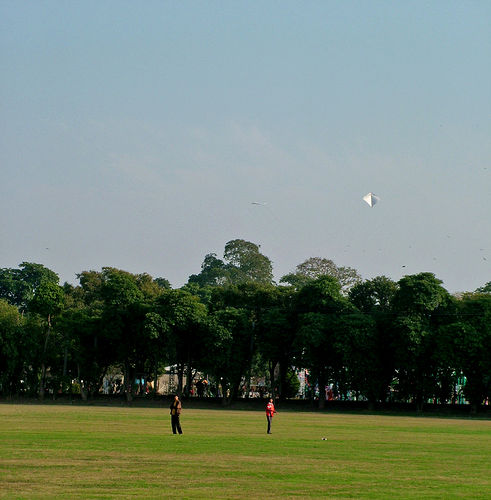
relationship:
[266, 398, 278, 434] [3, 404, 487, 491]
body standing in field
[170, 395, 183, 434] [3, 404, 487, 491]
body standing in field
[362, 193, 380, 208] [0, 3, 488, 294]
kite in sky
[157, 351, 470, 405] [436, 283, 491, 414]
buildings through tree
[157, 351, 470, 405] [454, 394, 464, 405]
buildings with shutters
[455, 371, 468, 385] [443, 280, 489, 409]
shutters by tree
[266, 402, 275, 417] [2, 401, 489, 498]
jacket on grass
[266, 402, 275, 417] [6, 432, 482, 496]
jacket on grass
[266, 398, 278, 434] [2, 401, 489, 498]
body on grass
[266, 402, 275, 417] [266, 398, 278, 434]
jacket on body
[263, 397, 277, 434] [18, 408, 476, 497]
body on grass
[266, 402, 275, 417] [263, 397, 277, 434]
jacket on body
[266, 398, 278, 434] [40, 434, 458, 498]
body on grass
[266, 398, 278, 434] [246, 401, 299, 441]
body wearing jacket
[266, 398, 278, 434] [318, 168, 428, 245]
body flying kite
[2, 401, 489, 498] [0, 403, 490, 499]
grass in field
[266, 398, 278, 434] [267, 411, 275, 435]
body wearing jeans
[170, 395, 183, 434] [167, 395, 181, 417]
body wearing jacket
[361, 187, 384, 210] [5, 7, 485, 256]
kite in sky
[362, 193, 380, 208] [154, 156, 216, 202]
kite in sky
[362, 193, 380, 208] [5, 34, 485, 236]
kite in sky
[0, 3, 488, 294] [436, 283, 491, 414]
sky over tree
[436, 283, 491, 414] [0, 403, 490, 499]
tree in field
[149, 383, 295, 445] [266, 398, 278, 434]
sun on body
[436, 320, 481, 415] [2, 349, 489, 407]
tree along side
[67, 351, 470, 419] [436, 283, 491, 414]
buildings behind tree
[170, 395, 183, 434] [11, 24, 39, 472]
body looks left